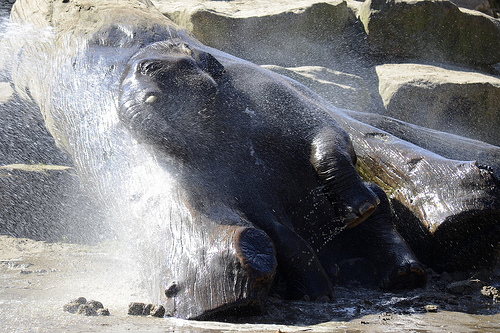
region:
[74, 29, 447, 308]
statute in the water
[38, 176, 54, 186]
water droplet being sprayed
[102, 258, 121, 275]
water droplet being sprayed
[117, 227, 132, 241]
water droplet being sprayed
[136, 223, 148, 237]
water droplet being sprayed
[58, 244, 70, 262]
water droplet being sprayed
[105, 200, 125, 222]
water droplet being sprayed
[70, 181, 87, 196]
water droplet being sprayed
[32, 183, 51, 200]
water droplet being sprayed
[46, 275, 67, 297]
water droplet being sprayed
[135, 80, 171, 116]
short left elephant tusk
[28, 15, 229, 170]
head of an elephant showering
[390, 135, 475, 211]
wet log glistening in the sun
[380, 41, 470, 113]
sunshine on a grey rock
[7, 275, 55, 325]
wet dirt with some sunshine on it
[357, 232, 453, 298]
elephant's back left foot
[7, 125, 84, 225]
water spray on rocks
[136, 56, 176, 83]
wet elephant left eye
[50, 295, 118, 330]
wet rocks in dirt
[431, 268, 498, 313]
wet rocks in shadows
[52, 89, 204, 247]
reflection on the rock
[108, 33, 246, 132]
artifact has a face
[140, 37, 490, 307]
artifact in between two rocks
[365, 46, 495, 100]
sun on the rocks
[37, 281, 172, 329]
rocks are small on the ground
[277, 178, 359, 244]
peice of wood between hands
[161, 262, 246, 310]
rough edge on the side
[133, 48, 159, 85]
eyes on the peice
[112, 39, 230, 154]
a face on the artifact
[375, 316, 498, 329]
dirt on the ground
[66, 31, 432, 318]
elephant leaning over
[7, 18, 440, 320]
elephant getting sprayed with water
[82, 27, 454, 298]
elephant that is wet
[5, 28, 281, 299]
several water droplets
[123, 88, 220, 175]
trunk is curled under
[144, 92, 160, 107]
small white tusk on the side of the trunk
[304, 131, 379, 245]
trunk is lifted off the ground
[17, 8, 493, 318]
elephant is leaning on the rocks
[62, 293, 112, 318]
small pile of rocks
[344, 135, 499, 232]
rock is wet